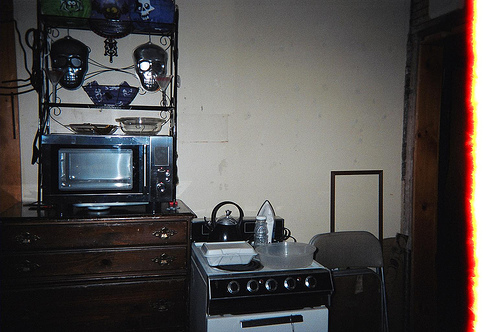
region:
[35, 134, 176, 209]
a black microwave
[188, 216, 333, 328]
a small stovetop and oven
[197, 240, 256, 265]
a foam food container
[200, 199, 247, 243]
a black and silver tea pot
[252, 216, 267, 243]
a clear plastic bottle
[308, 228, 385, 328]
a brown folding chair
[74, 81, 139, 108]
a blue patterned bowl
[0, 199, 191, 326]
a large wood dresser drawer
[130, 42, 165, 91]
a metal skull pan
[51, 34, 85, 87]
a metal skull pan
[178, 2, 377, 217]
the wall is white.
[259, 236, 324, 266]
plastic bowl on the stove.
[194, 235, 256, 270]
takeout box on the stove.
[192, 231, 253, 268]
takeout box is white.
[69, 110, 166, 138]
bowls on the microwave.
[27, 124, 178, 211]
microwave on a shelf.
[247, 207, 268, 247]
plastic bottle on stove.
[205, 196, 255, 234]
tea kettle on the stove.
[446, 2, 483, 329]
burn line on the picture.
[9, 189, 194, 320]
the desk is brown.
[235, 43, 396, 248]
the wall is white and visible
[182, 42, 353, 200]
the wall is white and visible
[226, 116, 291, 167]
the wall is white and visible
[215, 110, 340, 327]
the wall is white and visible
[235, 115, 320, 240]
the wall is white and visible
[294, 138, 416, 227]
black rectagular picture frame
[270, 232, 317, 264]
clear round plastic top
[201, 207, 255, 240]
black and silcer teapot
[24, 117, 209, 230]
silver microwave on dresser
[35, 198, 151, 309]
dark brown dresser with gold hinges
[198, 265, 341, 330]
black and white stovetop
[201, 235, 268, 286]
white chiese takeout box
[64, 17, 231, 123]
two silver skulls hanging from shelf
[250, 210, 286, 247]
back of iron head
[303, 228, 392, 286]
gray metal pullout chair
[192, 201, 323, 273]
stove top is white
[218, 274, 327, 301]
knobs on stove are black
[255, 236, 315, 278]
plastic container on stove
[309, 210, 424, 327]
fold-able chair next to stove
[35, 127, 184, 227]
toaster oven on dresser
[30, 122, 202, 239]
toaster oven is gray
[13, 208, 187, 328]
the dresser is brown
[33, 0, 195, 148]
metal rack behind toaster oven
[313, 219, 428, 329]
the chair is gray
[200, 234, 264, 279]
white to go box on stove top